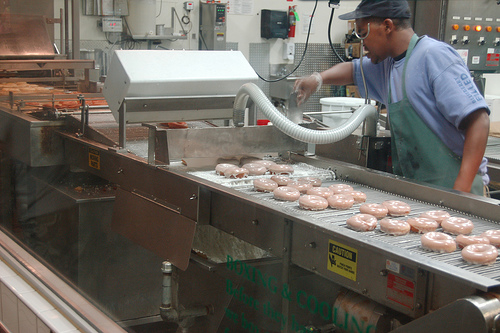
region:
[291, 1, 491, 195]
Man in green apron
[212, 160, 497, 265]
Glazed donuts on moving tray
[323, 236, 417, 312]
Warning stickers on equipment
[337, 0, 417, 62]
Black cap on man's head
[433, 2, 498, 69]
Many orange and black buttons on equipment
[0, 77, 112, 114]
Un-glazed donuts on moving tray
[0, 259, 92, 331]
White tiles on window sill wall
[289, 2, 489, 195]
Man wearing watch in blue shirt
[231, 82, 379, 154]
White hose attached to equipment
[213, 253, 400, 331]
Green writing on window glass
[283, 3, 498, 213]
Person making donuts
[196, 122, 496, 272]
Donuts are white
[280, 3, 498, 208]
Man wears a cap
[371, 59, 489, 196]
Apron is green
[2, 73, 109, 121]
Donuts are bown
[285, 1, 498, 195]
Worker has a glove in right hand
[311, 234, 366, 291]
Yellow caution sign in machine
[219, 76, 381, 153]
Tube is tan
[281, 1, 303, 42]
Fire emergency tank is red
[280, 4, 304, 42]
Emergency tank is hang on a wall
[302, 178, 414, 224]
donuts on a conveyer belt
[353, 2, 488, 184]
man in green apron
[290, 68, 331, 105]
plastic glove on hand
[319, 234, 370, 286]
caution sign on conveyer belt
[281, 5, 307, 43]
fire extinguisher on wall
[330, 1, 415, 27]
blue hat on man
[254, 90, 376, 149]
white hose over conveyer belt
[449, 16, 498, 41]
yellow buttons on silver box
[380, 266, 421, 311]
red sign on conveyer belt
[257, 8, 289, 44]
black box on wall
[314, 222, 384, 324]
Yellow caution sticker on belt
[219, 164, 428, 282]
Silver conveyor belt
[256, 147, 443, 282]
Glazed covered donuts on conveyor belt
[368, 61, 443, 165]
Man wearing blue shirt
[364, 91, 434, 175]
Man wearing green apron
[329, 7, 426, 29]
Man wearing black hat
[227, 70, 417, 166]
White tube near man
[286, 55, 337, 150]
Man wearing glove on hand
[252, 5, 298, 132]
Paper towel dispenser on wall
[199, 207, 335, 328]
Green writing on glass window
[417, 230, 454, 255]
Glazed doughnut coming down a conveyer belt.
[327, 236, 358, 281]
Yellow and black caution sticker on the side of a conveyer belt.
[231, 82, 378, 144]
Light gray colored hose going from one thing to another by the conveyer belt.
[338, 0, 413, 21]
Dark colored hat on a mans head.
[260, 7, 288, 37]
Paper towel dispenser machine on the wall.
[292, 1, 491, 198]
Man in light blue shirt standing at a doughnut conveyer belt.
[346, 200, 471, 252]
Eight glazed doughnuts coming down a conveyer belt.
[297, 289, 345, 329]
The word COOL in green letters.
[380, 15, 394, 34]
Left ear of a man working at a conveyer belt.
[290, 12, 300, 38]
Fire extinguisher on the wall beside a paper towel dispenser.